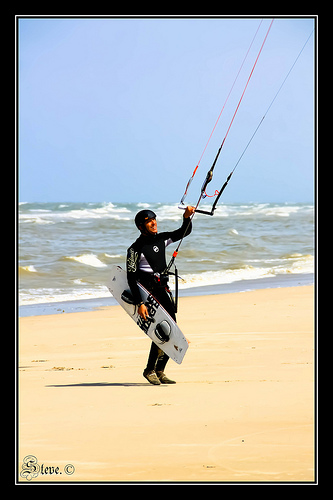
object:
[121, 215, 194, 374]
wetsuit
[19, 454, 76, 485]
copyright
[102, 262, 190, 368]
kiteboard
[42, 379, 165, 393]
shadow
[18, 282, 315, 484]
beach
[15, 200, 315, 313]
ocean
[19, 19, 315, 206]
sky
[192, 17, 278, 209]
cable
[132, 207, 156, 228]
helmet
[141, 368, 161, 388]
shoe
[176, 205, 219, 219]
handle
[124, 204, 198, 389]
man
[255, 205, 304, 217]
wave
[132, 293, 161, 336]
writing